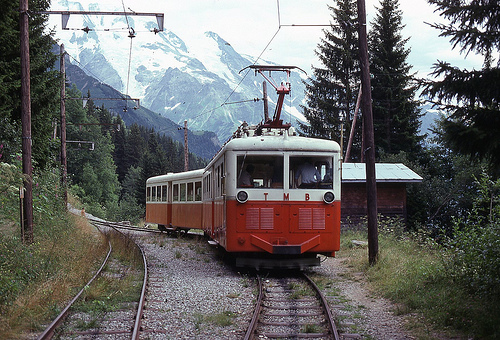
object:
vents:
[237, 204, 332, 233]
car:
[146, 126, 343, 272]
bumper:
[251, 235, 321, 255]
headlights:
[322, 190, 336, 204]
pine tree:
[294, 0, 375, 162]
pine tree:
[413, 0, 500, 181]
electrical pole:
[19, 0, 164, 244]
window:
[152, 186, 157, 202]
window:
[161, 185, 166, 201]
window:
[157, 186, 161, 202]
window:
[187, 182, 193, 201]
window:
[195, 182, 203, 202]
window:
[237, 155, 284, 189]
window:
[220, 162, 225, 195]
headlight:
[236, 190, 249, 204]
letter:
[264, 193, 269, 201]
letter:
[284, 192, 289, 200]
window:
[289, 155, 332, 189]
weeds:
[69, 224, 140, 336]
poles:
[17, 0, 35, 245]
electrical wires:
[60, 43, 138, 213]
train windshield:
[237, 154, 333, 189]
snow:
[48, 3, 310, 123]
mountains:
[49, 0, 448, 168]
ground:
[1, 212, 498, 338]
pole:
[356, 0, 379, 266]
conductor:
[295, 162, 321, 190]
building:
[315, 162, 423, 232]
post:
[357, 0, 378, 264]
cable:
[176, 0, 354, 131]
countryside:
[0, 0, 494, 338]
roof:
[314, 162, 422, 182]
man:
[294, 163, 321, 189]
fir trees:
[3, 3, 213, 240]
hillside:
[0, 38, 222, 231]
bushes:
[374, 173, 497, 336]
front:
[225, 135, 341, 255]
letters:
[305, 193, 309, 200]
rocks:
[110, 229, 349, 339]